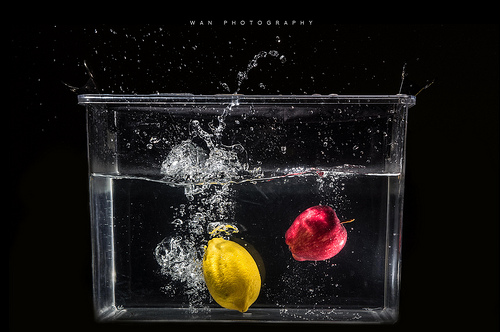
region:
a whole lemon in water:
[210, 225, 260, 310]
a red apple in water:
[285, 192, 355, 260]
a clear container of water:
[76, 96, 405, 324]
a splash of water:
[160, 33, 292, 164]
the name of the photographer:
[185, 16, 328, 30]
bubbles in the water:
[195, 199, 258, 252]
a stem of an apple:
[335, 211, 359, 228]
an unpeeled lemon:
[198, 240, 262, 313]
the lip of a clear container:
[71, 75, 416, 113]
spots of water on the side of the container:
[91, 107, 408, 158]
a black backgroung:
[17, 45, 64, 73]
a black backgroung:
[162, 28, 259, 56]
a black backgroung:
[355, 49, 440, 90]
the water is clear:
[117, 211, 171, 279]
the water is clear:
[287, 263, 347, 303]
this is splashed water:
[165, 146, 246, 186]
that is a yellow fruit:
[208, 228, 269, 306]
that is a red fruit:
[288, 201, 362, 269]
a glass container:
[100, 103, 405, 300]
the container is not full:
[108, 106, 406, 326]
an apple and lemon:
[133, 153, 391, 330]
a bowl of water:
[44, 110, 401, 321]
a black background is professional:
[43, 12, 312, 157]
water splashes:
[161, 134, 271, 247]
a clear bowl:
[74, 82, 469, 317]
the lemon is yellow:
[206, 234, 279, 330]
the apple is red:
[285, 172, 355, 327]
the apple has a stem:
[300, 173, 384, 312]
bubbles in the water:
[167, 178, 276, 289]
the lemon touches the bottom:
[178, 210, 253, 300]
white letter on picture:
[306, 18, 317, 27]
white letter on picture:
[298, 18, 305, 28]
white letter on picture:
[290, 18, 297, 26]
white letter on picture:
[282, 19, 290, 25]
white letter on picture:
[274, 19, 280, 27]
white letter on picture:
[246, 18, 255, 26]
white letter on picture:
[238, 18, 247, 26]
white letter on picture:
[229, 18, 238, 27]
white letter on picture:
[220, 18, 229, 28]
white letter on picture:
[207, 19, 213, 26]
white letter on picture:
[186, 17, 198, 27]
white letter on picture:
[196, 18, 204, 25]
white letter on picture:
[248, 18, 253, 28]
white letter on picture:
[255, 18, 262, 27]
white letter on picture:
[265, 17, 272, 27]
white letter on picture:
[272, 18, 282, 25]